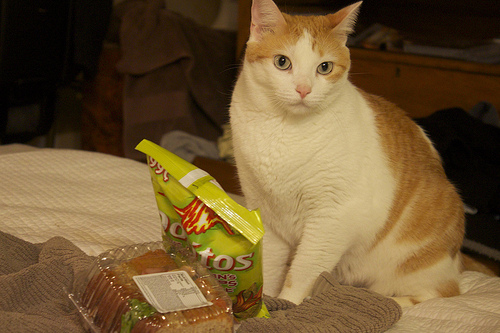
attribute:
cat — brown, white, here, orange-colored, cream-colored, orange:
[227, 2, 465, 308]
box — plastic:
[63, 238, 238, 332]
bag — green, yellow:
[134, 135, 273, 320]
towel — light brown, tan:
[118, 2, 238, 160]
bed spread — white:
[2, 141, 500, 332]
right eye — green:
[314, 59, 333, 74]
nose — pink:
[294, 84, 312, 96]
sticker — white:
[131, 270, 213, 313]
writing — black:
[135, 276, 207, 312]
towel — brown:
[0, 230, 400, 332]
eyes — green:
[273, 52, 335, 75]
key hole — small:
[391, 64, 404, 78]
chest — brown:
[345, 3, 499, 120]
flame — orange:
[176, 197, 230, 236]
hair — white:
[342, 10, 356, 36]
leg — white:
[283, 224, 348, 305]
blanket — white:
[1, 139, 499, 331]